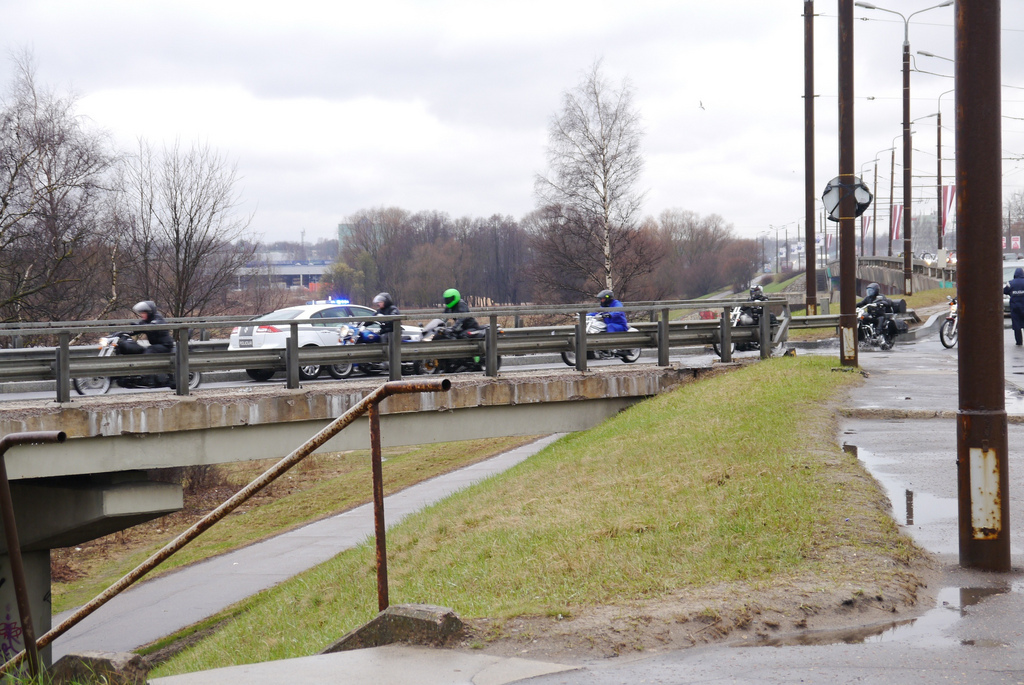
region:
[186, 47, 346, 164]
a view of sky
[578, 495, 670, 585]
a view of grass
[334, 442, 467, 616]
a view of rod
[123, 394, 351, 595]
a view of gate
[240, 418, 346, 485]
a view of iron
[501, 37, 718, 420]
a view of trees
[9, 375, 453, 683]
metal railing along steps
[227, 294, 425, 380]
police vehicle on the road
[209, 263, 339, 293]
large cement bridge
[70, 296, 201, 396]
motorcyclist going across a bridge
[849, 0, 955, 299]
tall street light on the side of the road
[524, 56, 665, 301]
deciduous tree with no leaves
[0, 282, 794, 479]
old cement and metal bridge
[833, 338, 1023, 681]
standing water on side of road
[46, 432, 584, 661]
walking trail under a bridge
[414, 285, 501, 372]
A person riding a motorcycle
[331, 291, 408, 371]
A person riding a motorcycle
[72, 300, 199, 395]
A person riding a motorcycle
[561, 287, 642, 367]
A person riding a motorcycle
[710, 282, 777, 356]
A person riding a motorcycle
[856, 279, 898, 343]
A person riding a motorcycle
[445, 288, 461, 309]
A green colored helmet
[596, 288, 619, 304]
A black colored helmet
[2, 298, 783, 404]
Metal safety rails on a bridge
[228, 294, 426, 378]
A white police car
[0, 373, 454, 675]
Rusted metal handrail on stairway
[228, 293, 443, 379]
White police car on road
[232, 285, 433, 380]
police car with sirens on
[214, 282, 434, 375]
police car with sirens on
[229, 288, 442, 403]
police car with sirens on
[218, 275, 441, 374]
police car with sirens on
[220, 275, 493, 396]
police car with sirens on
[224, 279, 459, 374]
police car with sirens on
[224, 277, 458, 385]
police car with sirens on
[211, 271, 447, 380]
police car with sirens on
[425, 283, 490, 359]
man wearing a green helmet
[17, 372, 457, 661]
iron railing by the steps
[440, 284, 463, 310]
the helmet is green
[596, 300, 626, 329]
the jacket is blue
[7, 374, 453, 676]
a rusty hand rail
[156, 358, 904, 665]
a patch of grass near a bridge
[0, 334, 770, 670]
a bridge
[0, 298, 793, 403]
a metal gate on a bridge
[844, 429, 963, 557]
a puddle beside the road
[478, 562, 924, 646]
a patch of mud near stairs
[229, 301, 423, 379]
a white car on a bridge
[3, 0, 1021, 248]
a cloudy white sky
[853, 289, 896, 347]
a motorcycle crossing a bridge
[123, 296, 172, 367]
a man on a motorcycle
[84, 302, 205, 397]
A person on a motorcycle.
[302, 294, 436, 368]
A person on a motorcycle.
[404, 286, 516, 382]
A person on a motorcycle.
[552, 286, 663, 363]
A person on a motorcycle.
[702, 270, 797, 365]
A person on a motorcycle.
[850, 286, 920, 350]
A person on a motorcycle.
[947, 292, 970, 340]
A person on a motorcycle.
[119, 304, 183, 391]
A person is sitting down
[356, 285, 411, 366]
A person is sitting down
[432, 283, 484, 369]
A person is sitting down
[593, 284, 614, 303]
the helmet is black